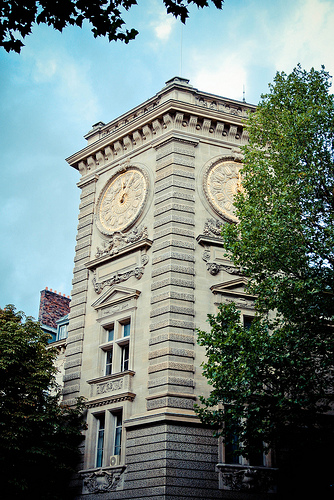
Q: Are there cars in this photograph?
A: No, there are no cars.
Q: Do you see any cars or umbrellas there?
A: No, there are no cars or umbrellas.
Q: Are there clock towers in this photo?
A: Yes, there is a clock tower.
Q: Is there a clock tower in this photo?
A: Yes, there is a clock tower.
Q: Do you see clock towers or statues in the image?
A: Yes, there is a clock tower.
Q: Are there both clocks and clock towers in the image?
A: Yes, there are both a clock tower and a clock.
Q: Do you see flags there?
A: No, there are no flags.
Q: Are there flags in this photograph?
A: No, there are no flags.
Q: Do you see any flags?
A: No, there are no flags.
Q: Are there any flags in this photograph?
A: No, there are no flags.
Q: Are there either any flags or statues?
A: No, there are no flags or statues.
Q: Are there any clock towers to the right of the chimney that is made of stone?
A: Yes, there is a clock tower to the right of the chimney.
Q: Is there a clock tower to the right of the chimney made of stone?
A: Yes, there is a clock tower to the right of the chimney.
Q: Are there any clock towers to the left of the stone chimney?
A: No, the clock tower is to the right of the chimney.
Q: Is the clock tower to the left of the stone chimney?
A: No, the clock tower is to the right of the chimney.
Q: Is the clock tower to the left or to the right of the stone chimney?
A: The clock tower is to the right of the chimney.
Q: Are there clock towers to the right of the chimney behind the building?
A: Yes, there is a clock tower to the right of the chimney.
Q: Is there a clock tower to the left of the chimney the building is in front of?
A: No, the clock tower is to the right of the chimney.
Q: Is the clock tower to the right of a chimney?
A: Yes, the clock tower is to the right of a chimney.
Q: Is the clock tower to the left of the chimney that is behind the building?
A: No, the clock tower is to the right of the chimney.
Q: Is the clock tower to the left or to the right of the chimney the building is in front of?
A: The clock tower is to the right of the chimney.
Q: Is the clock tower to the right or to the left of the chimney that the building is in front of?
A: The clock tower is to the right of the chimney.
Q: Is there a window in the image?
A: Yes, there are windows.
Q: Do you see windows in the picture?
A: Yes, there are windows.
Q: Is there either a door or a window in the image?
A: Yes, there are windows.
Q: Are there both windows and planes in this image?
A: No, there are windows but no airplanes.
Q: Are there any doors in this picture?
A: No, there are no doors.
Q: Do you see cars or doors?
A: No, there are no doors or cars.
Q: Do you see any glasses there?
A: No, there are no glasses.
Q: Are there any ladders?
A: No, there are no ladders.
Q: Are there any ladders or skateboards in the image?
A: No, there are no ladders or skateboards.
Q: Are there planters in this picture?
A: No, there are no planters.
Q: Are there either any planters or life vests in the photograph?
A: No, there are no planters or life vests.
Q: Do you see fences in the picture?
A: No, there are no fences.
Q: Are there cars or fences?
A: No, there are no fences or cars.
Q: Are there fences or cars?
A: No, there are no fences or cars.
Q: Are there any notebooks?
A: No, there are no notebooks.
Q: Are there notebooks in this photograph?
A: No, there are no notebooks.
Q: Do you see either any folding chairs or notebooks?
A: No, there are no notebooks or folding chairs.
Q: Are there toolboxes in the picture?
A: No, there are no toolboxes.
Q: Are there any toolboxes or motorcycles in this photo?
A: No, there are no toolboxes or motorcycles.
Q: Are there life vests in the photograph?
A: No, there are no life vests.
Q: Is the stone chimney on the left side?
A: Yes, the chimney is on the left of the image.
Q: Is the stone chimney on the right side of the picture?
A: No, the chimney is on the left of the image.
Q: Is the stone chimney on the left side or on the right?
A: The chimney is on the left of the image.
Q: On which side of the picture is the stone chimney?
A: The chimney is on the left of the image.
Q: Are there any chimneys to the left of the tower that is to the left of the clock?
A: Yes, there is a chimney to the left of the tower.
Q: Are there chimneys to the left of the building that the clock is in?
A: Yes, there is a chimney to the left of the tower.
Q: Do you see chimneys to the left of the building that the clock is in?
A: Yes, there is a chimney to the left of the tower.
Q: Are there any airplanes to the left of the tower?
A: No, there is a chimney to the left of the tower.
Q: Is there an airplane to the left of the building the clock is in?
A: No, there is a chimney to the left of the tower.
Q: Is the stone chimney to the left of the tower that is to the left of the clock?
A: Yes, the chimney is to the left of the tower.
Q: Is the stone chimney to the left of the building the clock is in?
A: Yes, the chimney is to the left of the tower.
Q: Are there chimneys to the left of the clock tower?
A: Yes, there is a chimney to the left of the clock tower.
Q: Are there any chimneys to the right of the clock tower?
A: No, the chimney is to the left of the clock tower.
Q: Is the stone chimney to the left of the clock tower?
A: Yes, the chimney is to the left of the clock tower.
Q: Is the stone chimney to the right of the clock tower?
A: No, the chimney is to the left of the clock tower.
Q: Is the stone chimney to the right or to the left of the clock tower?
A: The chimney is to the left of the clock tower.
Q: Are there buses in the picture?
A: No, there are no buses.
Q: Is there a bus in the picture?
A: No, there are no buses.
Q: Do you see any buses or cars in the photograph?
A: No, there are no buses or cars.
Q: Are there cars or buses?
A: No, there are no buses or cars.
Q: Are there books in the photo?
A: No, there are no books.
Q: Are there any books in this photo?
A: No, there are no books.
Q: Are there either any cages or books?
A: No, there are no books or cages.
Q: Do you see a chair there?
A: No, there are no chairs.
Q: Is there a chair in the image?
A: No, there are no chairs.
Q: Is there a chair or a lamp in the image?
A: No, there are no chairs or lamps.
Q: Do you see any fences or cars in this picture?
A: No, there are no fences or cars.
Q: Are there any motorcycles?
A: No, there are no motorcycles.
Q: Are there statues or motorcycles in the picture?
A: No, there are no motorcycles or statues.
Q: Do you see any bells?
A: No, there are no bells.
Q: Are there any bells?
A: No, there are no bells.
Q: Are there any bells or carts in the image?
A: No, there are no bells or carts.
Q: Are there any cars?
A: No, there are no cars.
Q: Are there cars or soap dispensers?
A: No, there are no cars or soap dispensers.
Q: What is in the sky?
A: The clouds are in the sky.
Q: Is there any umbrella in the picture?
A: No, there are no umbrellas.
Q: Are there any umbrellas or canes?
A: No, there are no umbrellas or canes.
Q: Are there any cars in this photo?
A: No, there are no cars.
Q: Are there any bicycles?
A: No, there are no bicycles.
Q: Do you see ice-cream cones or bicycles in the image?
A: No, there are no bicycles or ice-cream cones.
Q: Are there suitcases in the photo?
A: No, there are no suitcases.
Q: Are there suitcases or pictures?
A: No, there are no suitcases or pictures.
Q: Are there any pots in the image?
A: No, there are no pots.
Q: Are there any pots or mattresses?
A: No, there are no pots or mattresses.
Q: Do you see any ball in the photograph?
A: No, there are no balls.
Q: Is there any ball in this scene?
A: No, there are no balls.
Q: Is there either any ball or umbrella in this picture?
A: No, there are no balls or umbrellas.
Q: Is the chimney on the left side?
A: Yes, the chimney is on the left of the image.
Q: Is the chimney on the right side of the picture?
A: No, the chimney is on the left of the image.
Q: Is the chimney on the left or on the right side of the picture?
A: The chimney is on the left of the image.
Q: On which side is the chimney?
A: The chimney is on the left of the image.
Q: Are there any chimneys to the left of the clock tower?
A: Yes, there is a chimney to the left of the clock tower.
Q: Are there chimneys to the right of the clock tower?
A: No, the chimney is to the left of the clock tower.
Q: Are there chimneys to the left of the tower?
A: Yes, there is a chimney to the left of the tower.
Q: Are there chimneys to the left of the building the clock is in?
A: Yes, there is a chimney to the left of the tower.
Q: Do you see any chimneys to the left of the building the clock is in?
A: Yes, there is a chimney to the left of the tower.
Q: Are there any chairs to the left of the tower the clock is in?
A: No, there is a chimney to the left of the tower.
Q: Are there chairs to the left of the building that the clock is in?
A: No, there is a chimney to the left of the tower.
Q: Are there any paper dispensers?
A: No, there are no paper dispensers.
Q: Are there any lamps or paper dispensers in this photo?
A: No, there are no paper dispensers or lamps.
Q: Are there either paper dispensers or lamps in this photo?
A: No, there are no paper dispensers or lamps.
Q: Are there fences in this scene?
A: No, there are no fences.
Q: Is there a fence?
A: No, there are no fences.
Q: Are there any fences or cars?
A: No, there are no fences or cars.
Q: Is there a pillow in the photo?
A: No, there are no pillows.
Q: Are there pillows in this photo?
A: No, there are no pillows.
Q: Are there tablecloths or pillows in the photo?
A: No, there are no pillows or tablecloths.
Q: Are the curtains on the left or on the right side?
A: The curtains are on the left of the image.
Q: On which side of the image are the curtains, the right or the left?
A: The curtains are on the left of the image.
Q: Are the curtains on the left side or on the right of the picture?
A: The curtains are on the left of the image.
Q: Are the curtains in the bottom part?
A: Yes, the curtains are in the bottom of the image.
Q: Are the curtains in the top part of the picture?
A: No, the curtains are in the bottom of the image.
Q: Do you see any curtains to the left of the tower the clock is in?
A: Yes, there are curtains to the left of the tower.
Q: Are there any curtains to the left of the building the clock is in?
A: Yes, there are curtains to the left of the tower.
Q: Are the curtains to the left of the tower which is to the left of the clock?
A: Yes, the curtains are to the left of the tower.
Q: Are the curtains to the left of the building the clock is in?
A: Yes, the curtains are to the left of the tower.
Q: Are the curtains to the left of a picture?
A: No, the curtains are to the left of the tower.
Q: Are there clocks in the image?
A: Yes, there is a clock.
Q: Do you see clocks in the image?
A: Yes, there is a clock.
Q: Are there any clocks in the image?
A: Yes, there is a clock.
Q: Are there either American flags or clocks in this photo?
A: Yes, there is a clock.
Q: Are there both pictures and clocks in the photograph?
A: No, there is a clock but no pictures.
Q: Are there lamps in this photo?
A: No, there are no lamps.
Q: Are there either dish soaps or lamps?
A: No, there are no lamps or dish soaps.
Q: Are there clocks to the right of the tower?
A: Yes, there is a clock to the right of the tower.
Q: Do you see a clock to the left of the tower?
A: No, the clock is to the right of the tower.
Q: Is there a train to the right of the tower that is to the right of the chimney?
A: No, there is a clock to the right of the tower.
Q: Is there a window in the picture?
A: Yes, there is a window.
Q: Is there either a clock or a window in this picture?
A: Yes, there is a window.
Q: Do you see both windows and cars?
A: No, there is a window but no cars.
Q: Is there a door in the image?
A: No, there are no doors.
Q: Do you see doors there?
A: No, there are no doors.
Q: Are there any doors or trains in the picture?
A: No, there are no doors or trains.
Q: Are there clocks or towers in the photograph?
A: Yes, there is a clock.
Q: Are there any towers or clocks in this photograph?
A: Yes, there is a clock.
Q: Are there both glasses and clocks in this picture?
A: No, there is a clock but no glasses.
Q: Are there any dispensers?
A: No, there are no dispensers.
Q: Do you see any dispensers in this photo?
A: No, there are no dispensers.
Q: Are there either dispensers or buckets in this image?
A: No, there are no dispensers or buckets.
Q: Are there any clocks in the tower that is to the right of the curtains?
A: Yes, there is a clock in the tower.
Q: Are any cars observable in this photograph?
A: No, there are no cars.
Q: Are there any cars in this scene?
A: No, there are no cars.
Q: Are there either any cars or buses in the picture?
A: No, there are no cars or buses.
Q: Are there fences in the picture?
A: No, there are no fences.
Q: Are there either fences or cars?
A: No, there are no fences or cars.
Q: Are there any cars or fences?
A: No, there are no fences or cars.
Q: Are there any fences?
A: No, there are no fences.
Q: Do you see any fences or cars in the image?
A: No, there are no fences or cars.